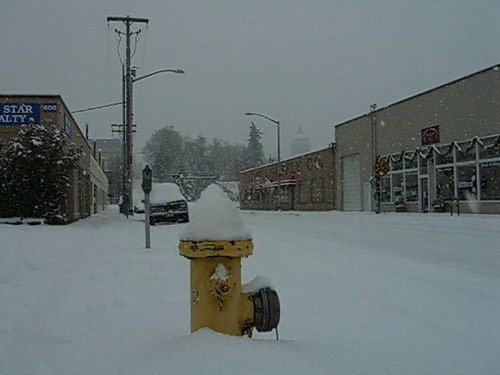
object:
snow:
[0, 180, 500, 375]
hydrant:
[177, 223, 282, 339]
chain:
[252, 327, 286, 348]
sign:
[1, 99, 43, 129]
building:
[238, 145, 337, 211]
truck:
[137, 177, 189, 225]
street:
[0, 210, 500, 375]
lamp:
[157, 62, 190, 80]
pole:
[129, 63, 134, 220]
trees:
[240, 122, 266, 172]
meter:
[140, 162, 154, 248]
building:
[0, 94, 111, 228]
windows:
[476, 160, 499, 203]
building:
[333, 64, 500, 215]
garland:
[375, 130, 500, 166]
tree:
[2, 122, 87, 224]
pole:
[143, 193, 152, 250]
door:
[341, 153, 363, 214]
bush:
[4, 127, 84, 225]